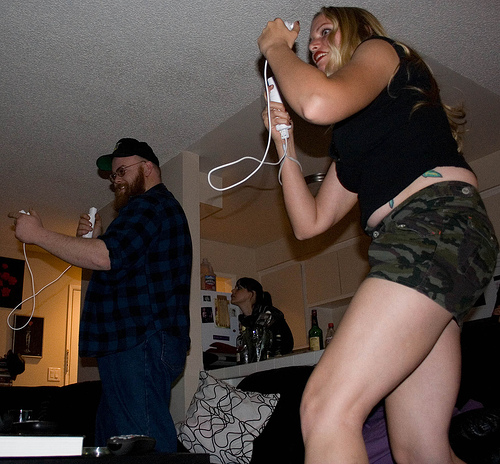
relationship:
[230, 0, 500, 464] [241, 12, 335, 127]
girl has controllers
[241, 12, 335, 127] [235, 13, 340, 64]
controllers in hands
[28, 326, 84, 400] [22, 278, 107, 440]
switch on wall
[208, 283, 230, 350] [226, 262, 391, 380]
refrigerator in kitchen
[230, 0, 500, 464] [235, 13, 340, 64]
girl has hands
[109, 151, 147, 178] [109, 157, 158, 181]
man has eyeglasses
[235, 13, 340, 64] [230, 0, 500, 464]
hands of girl